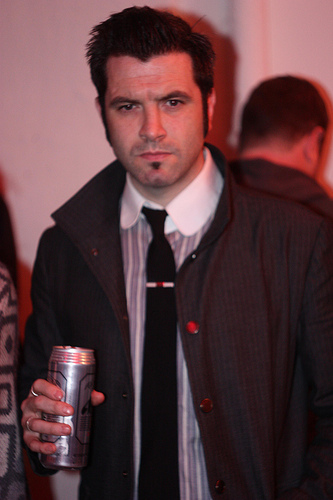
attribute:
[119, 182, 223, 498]
shirt — striped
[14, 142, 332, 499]
jacket — dark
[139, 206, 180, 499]
tie — clip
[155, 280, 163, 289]
detail — red 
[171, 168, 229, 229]
colar — white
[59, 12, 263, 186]
guy — facing other side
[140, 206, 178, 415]
tie — black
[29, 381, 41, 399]
ring — silver  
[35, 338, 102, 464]
can — silver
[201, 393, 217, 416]
button — red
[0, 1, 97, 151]
wall — background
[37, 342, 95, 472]
can — silver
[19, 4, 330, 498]
man — man's 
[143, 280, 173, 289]
tack — tie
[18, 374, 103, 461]
finger — index 